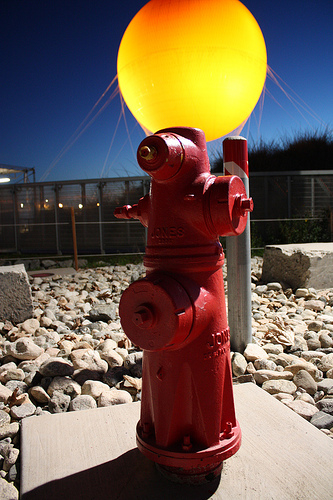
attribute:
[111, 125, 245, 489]
fire hydrant — Red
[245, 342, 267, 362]
rock — Cream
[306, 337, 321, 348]
rock — Cream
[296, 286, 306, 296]
rock — Cream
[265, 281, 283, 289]
rock — Cream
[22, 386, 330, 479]
base — hydrant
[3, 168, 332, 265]
fence — grey 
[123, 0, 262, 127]
balloon — orange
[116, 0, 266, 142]
balloon — large, orange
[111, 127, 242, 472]
hydrant — Red fire 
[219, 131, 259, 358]
pole — white , red 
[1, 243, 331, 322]
bricks — grey 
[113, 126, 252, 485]
hydrant — fire hydrant, red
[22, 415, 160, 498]
slab — concrete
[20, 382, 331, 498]
wood base — brown wood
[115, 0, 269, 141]
baloon — orange, large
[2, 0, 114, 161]
sky — dark blue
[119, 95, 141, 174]
line — large